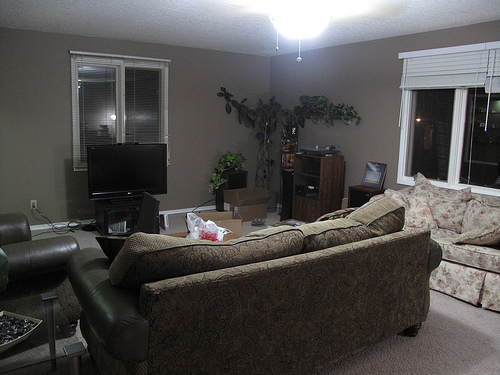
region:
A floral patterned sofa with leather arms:
[81, 215, 444, 367]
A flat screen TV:
[87, 138, 172, 198]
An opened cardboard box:
[220, 186, 280, 221]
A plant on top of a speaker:
[215, 151, 251, 189]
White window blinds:
[399, 61, 498, 93]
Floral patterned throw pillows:
[401, 185, 498, 235]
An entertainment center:
[296, 150, 348, 221]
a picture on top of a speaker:
[361, 158, 386, 190]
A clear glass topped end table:
[6, 298, 93, 368]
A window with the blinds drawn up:
[397, 65, 494, 186]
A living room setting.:
[12, 21, 467, 350]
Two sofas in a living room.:
[54, 169, 491, 347]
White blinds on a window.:
[386, 38, 496, 126]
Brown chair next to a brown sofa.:
[2, 202, 94, 339]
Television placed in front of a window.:
[59, 35, 190, 230]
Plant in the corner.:
[208, 60, 317, 202]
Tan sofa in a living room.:
[432, 187, 494, 294]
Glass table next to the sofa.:
[2, 284, 94, 369]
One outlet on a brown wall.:
[23, 191, 45, 226]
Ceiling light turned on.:
[218, 4, 385, 69]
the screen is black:
[74, 143, 184, 211]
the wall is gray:
[167, 44, 265, 207]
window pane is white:
[61, 44, 191, 235]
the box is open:
[212, 178, 289, 223]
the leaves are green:
[207, 138, 232, 191]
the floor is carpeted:
[426, 307, 469, 367]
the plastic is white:
[184, 210, 239, 259]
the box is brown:
[220, 178, 278, 232]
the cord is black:
[31, 205, 96, 238]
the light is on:
[217, 10, 366, 95]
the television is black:
[85, 136, 177, 211]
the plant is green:
[199, 144, 250, 204]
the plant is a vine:
[203, 141, 245, 200]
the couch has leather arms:
[61, 245, 155, 370]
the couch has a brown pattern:
[58, 190, 448, 374]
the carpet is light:
[1, 198, 499, 372]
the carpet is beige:
[1, 200, 499, 374]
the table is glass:
[0, 285, 91, 370]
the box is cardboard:
[215, 181, 271, 227]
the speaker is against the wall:
[215, 168, 247, 213]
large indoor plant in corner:
[220, 66, 347, 192]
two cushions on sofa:
[78, 218, 440, 371]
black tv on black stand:
[78, 128, 213, 245]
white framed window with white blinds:
[395, 34, 498, 191]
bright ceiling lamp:
[225, 1, 371, 80]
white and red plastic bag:
[175, 198, 240, 261]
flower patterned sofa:
[388, 170, 498, 301]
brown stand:
[281, 131, 350, 234]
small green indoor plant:
[203, 150, 258, 225]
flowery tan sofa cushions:
[406, 172, 488, 249]